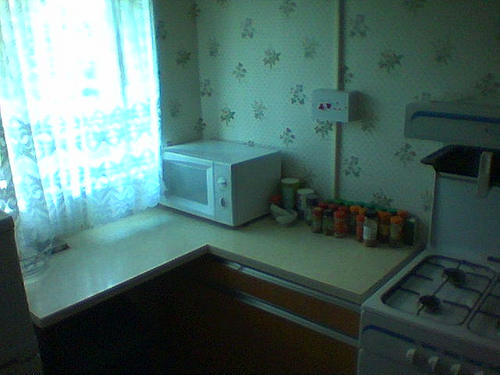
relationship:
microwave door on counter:
[159, 152, 215, 221] [18, 197, 425, 327]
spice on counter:
[377, 209, 393, 242] [216, 220, 404, 294]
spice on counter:
[388, 215, 403, 247] [216, 220, 404, 294]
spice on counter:
[358, 207, 381, 248] [216, 220, 404, 294]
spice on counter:
[330, 209, 347, 237] [216, 220, 404, 294]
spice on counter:
[310, 206, 325, 233] [216, 220, 404, 294]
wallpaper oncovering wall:
[149, 0, 498, 243] [371, 40, 461, 88]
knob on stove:
[405, 347, 424, 369] [357, 173, 498, 373]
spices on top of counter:
[306, 195, 409, 240] [252, 217, 419, 323]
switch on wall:
[310, 87, 352, 124] [146, 0, 498, 268]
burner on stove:
[380, 253, 490, 330] [356, 97, 498, 373]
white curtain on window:
[5, 7, 162, 214] [7, 7, 179, 204]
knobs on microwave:
[213, 176, 229, 212] [154, 130, 279, 232]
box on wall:
[296, 82, 373, 132] [371, 40, 461, 88]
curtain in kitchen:
[4, 9, 164, 218] [3, 1, 493, 363]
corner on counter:
[183, 232, 231, 259] [18, 197, 425, 327]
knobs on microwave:
[216, 177, 228, 188] [152, 134, 289, 233]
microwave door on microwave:
[159, 148, 219, 224] [152, 134, 289, 233]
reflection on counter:
[69, 208, 168, 315] [159, 86, 377, 223]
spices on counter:
[277, 170, 415, 252] [18, 180, 435, 317]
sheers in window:
[6, 0, 174, 252] [18, 18, 200, 259]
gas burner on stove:
[439, 260, 466, 290] [352, 242, 497, 374]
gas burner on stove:
[417, 291, 443, 317] [352, 242, 497, 374]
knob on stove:
[405, 347, 424, 369] [350, 143, 499, 373]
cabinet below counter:
[207, 257, 359, 373] [18, 197, 425, 327]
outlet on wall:
[308, 86, 358, 123] [301, 37, 454, 150]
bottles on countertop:
[271, 168, 421, 257] [12, 198, 418, 324]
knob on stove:
[405, 347, 422, 365] [356, 97, 498, 373]